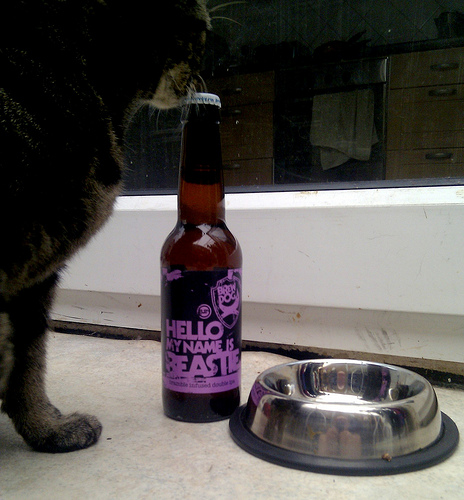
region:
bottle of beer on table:
[156, 87, 250, 428]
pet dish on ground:
[223, 348, 462, 481]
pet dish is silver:
[225, 352, 463, 483]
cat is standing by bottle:
[2, 1, 242, 462]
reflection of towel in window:
[304, 91, 381, 172]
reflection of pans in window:
[309, 26, 370, 58]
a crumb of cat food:
[366, 426, 425, 478]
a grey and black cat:
[8, 8, 341, 467]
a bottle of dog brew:
[160, 68, 304, 419]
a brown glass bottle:
[126, 69, 310, 407]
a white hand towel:
[259, 51, 420, 186]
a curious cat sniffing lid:
[80, 10, 286, 302]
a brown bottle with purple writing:
[124, 63, 287, 464]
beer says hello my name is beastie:
[161, 92, 243, 421]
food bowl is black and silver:
[227, 359, 458, 473]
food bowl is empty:
[231, 359, 461, 474]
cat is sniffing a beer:
[0, 3, 209, 453]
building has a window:
[118, 5, 462, 193]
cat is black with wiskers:
[0, 0, 210, 455]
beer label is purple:
[160, 268, 241, 391]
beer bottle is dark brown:
[161, 105, 240, 421]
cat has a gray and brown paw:
[8, 394, 102, 454]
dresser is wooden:
[388, 51, 462, 177]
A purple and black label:
[154, 254, 245, 400]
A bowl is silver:
[221, 348, 457, 478]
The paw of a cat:
[5, 390, 109, 459]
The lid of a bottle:
[173, 84, 224, 113]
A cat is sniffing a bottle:
[0, 0, 244, 459]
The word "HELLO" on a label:
[156, 308, 226, 343]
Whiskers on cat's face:
[143, 63, 212, 133]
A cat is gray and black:
[0, 0, 212, 459]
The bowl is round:
[221, 345, 457, 478]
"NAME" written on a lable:
[176, 329, 224, 358]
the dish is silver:
[271, 352, 433, 457]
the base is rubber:
[243, 443, 425, 470]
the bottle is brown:
[173, 92, 228, 422]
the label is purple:
[163, 265, 241, 392]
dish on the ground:
[239, 334, 428, 488]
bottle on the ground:
[157, 88, 239, 432]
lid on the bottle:
[188, 92, 218, 113]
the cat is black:
[2, 4, 108, 446]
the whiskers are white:
[159, 62, 206, 125]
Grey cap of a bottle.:
[178, 90, 221, 108]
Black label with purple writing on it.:
[159, 261, 243, 395]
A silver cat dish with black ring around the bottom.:
[227, 357, 458, 476]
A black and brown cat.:
[0, 1, 213, 454]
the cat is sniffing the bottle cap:
[3, 4, 246, 434]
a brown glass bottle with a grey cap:
[164, 92, 240, 418]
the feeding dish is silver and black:
[230, 359, 455, 475]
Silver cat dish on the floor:
[220, 354, 456, 469]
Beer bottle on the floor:
[149, 87, 251, 425]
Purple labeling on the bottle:
[157, 259, 247, 396]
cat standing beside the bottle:
[0, 2, 211, 440]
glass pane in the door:
[91, 7, 453, 193]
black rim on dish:
[220, 395, 461, 479]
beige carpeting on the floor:
[0, 322, 458, 497]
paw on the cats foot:
[13, 403, 111, 462]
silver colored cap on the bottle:
[178, 86, 225, 109]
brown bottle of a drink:
[150, 85, 247, 416]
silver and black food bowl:
[237, 350, 433, 481]